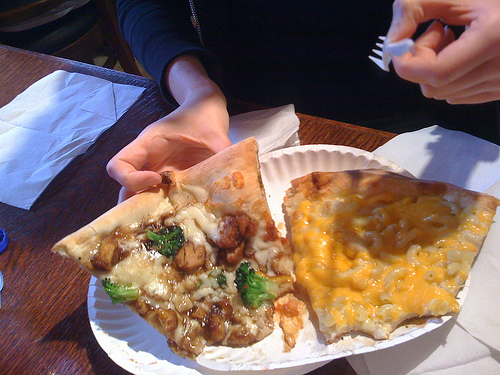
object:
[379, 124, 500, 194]
napkins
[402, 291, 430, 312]
cheese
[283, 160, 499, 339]
pizza.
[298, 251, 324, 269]
sauce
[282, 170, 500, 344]
macaroni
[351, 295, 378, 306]
cheese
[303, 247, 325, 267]
cheese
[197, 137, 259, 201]
crust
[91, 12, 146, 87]
leg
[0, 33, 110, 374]
part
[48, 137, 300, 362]
pizza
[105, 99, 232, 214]
hand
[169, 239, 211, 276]
mushroom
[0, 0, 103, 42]
camera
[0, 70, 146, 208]
napkin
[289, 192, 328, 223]
sauce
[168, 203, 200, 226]
cheese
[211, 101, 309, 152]
napkins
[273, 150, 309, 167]
paper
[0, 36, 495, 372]
table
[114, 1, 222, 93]
arm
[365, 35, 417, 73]
fork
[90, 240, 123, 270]
chicken topping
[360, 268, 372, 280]
sauce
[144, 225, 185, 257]
broccoli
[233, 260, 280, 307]
broccoli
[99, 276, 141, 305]
broccoli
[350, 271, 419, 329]
sauce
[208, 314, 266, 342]
sauce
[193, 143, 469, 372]
paper plate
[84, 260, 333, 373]
paper plate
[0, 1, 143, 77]
chair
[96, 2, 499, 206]
man